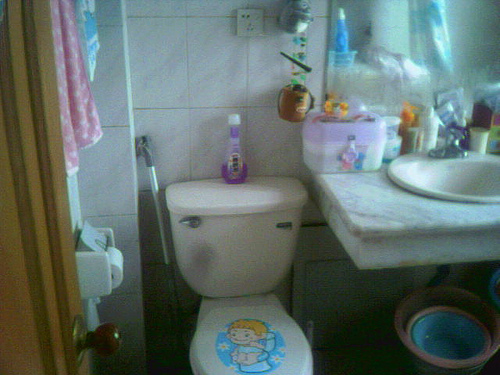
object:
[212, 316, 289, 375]
picture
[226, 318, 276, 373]
child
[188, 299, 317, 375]
toilet lid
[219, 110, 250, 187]
cleaning liquid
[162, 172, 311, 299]
toilet tank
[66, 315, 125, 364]
handle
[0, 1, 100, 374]
door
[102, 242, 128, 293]
roll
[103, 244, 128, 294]
toilet paper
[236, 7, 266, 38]
outlet cover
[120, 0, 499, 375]
wall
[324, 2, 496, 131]
mirror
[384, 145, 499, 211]
sink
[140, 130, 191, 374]
mop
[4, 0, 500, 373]
bathroom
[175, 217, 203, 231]
handle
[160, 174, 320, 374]
toilet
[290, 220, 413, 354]
vent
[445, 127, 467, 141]
handle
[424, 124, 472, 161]
faucet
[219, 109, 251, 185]
bottle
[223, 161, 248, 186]
liquid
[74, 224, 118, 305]
holder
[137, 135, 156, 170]
handle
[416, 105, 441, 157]
bottle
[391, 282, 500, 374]
pot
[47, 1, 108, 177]
towel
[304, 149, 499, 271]
counter